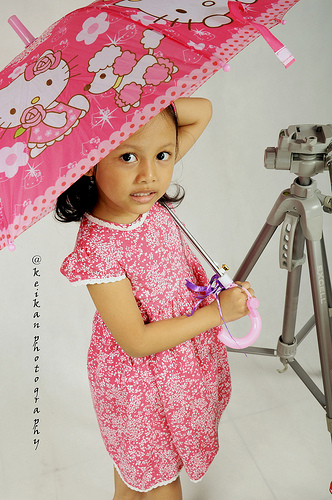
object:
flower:
[124, 414, 142, 434]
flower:
[157, 447, 175, 473]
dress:
[60, 214, 231, 492]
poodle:
[83, 28, 180, 114]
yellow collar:
[111, 73, 122, 91]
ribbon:
[185, 273, 223, 313]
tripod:
[263, 122, 330, 498]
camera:
[263, 122, 330, 184]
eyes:
[119, 152, 139, 164]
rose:
[20, 104, 47, 129]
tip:
[6, 15, 34, 47]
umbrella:
[0, 1, 297, 352]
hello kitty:
[0, 50, 89, 158]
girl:
[53, 96, 255, 499]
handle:
[216, 291, 263, 349]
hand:
[216, 280, 255, 324]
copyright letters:
[31, 255, 42, 452]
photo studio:
[1, 0, 331, 500]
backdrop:
[293, 0, 331, 126]